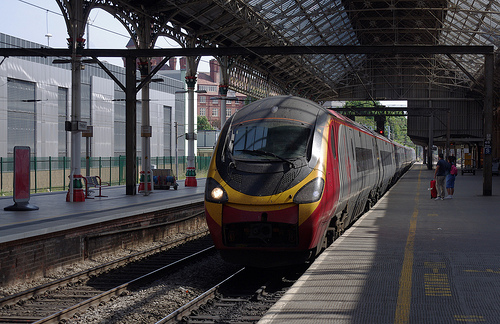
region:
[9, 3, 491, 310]
A commuter train at a train stop.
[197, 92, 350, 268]
Head of a commuter train.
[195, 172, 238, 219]
Headlight of a commuter train.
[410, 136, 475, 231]
People standing on the train platform at a station.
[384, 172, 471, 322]
Yellow markings and lettering on the platform at a train stop.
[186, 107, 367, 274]
Train with yellow and red curved designs.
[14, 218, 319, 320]
Iron train tracks at a train stop.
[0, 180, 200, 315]
Edge of a platform at a train stop.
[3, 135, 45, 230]
Red signage placed on a platform at a train stop.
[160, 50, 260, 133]
A large building that's behind a train stop.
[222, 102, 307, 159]
window on train is wid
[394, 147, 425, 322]
yellow lines on platform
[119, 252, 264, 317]
tracks for train to go on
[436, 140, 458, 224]
two people waiting for train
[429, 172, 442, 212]
red luggage by man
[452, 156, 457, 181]
lady in pink shirt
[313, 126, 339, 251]
side of train is red stripe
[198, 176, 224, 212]
one light is on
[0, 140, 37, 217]
sign on platform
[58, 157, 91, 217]
pole with green and red on bottom